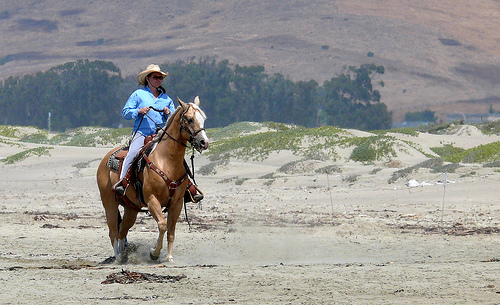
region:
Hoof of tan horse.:
[146, 248, 159, 265]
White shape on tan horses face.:
[190, 105, 209, 147]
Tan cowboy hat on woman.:
[134, 63, 171, 82]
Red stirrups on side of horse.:
[108, 150, 145, 197]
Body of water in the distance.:
[393, 110, 499, 132]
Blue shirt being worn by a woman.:
[121, 83, 177, 139]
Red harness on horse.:
[140, 148, 192, 214]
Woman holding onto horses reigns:
[138, 103, 193, 157]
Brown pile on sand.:
[99, 266, 187, 290]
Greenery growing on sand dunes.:
[234, 129, 315, 154]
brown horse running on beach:
[71, 91, 211, 287]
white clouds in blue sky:
[6, 2, 51, 47]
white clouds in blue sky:
[342, 31, 379, 63]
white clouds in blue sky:
[435, 69, 476, 110]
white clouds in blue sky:
[355, 35, 423, 80]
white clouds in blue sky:
[304, 28, 348, 72]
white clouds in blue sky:
[248, 36, 302, 84]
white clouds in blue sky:
[158, 28, 245, 60]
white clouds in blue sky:
[71, 23, 141, 73]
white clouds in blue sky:
[342, 46, 377, 68]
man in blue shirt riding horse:
[90, 59, 215, 271]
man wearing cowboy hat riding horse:
[94, 51, 215, 267]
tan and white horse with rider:
[92, 60, 214, 268]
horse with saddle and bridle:
[95, 60, 210, 267]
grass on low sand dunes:
[244, 113, 471, 185]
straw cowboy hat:
[134, 60, 170, 85]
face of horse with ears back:
[175, 89, 213, 155]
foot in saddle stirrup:
[111, 175, 132, 195]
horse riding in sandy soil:
[80, 57, 215, 267]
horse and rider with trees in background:
[93, 62, 212, 271]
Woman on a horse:
[96, 60, 203, 260]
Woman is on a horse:
[90, 56, 210, 262]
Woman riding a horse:
[91, 60, 211, 265]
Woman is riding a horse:
[90, 55, 211, 265]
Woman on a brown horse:
[92, 60, 213, 266]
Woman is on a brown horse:
[97, 58, 212, 265]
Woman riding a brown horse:
[94, 60, 214, 266]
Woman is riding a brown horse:
[92, 61, 212, 266]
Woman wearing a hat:
[130, 60, 172, 85]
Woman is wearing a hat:
[135, 60, 167, 89]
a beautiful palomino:
[84, 63, 228, 269]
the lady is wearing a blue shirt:
[114, 52, 217, 202]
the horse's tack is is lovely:
[79, 67, 229, 280]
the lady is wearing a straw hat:
[118, 62, 186, 97]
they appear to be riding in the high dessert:
[111, 48, 486, 303]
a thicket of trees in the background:
[41, 56, 366, 127]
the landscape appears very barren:
[242, 166, 462, 287]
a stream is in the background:
[385, 115, 492, 127]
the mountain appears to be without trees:
[78, 3, 430, 65]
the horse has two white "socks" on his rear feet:
[91, 227, 148, 271]